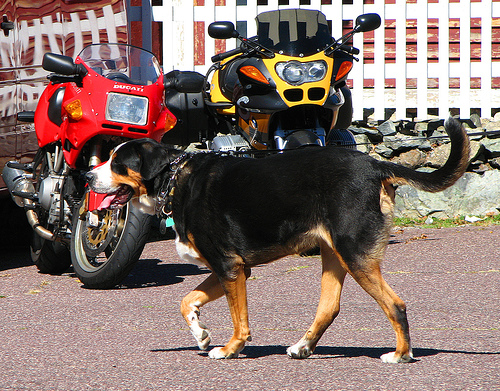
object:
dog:
[83, 116, 470, 363]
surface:
[1, 39, 204, 288]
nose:
[82, 171, 97, 182]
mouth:
[103, 185, 128, 202]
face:
[81, 140, 149, 210]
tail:
[371, 117, 475, 192]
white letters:
[113, 83, 144, 92]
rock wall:
[342, 115, 500, 217]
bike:
[161, 6, 381, 237]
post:
[394, 1, 410, 119]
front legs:
[200, 226, 252, 347]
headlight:
[275, 57, 326, 81]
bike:
[8, 37, 211, 284]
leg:
[179, 262, 249, 333]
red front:
[31, 42, 179, 170]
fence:
[0, 0, 499, 122]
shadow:
[145, 326, 498, 379]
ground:
[0, 203, 498, 389]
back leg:
[341, 226, 410, 350]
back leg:
[296, 241, 346, 344]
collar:
[155, 146, 190, 234]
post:
[372, 0, 384, 118]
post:
[162, 0, 195, 73]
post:
[459, 0, 471, 120]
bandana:
[147, 142, 213, 218]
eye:
[114, 158, 128, 166]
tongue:
[96, 192, 115, 212]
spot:
[92, 166, 115, 194]